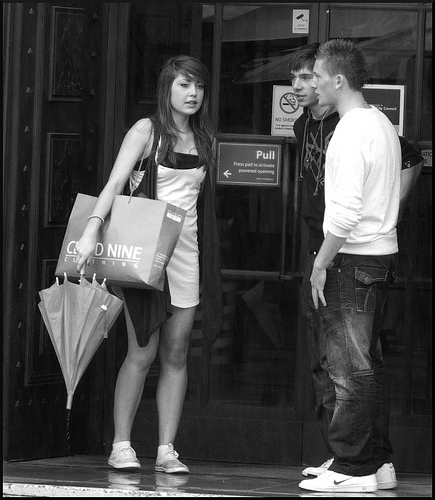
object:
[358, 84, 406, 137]
sign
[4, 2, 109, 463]
door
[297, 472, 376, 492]
sneaker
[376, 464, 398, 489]
sneaker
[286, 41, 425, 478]
guy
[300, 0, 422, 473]
door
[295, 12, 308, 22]
camera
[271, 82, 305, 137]
sign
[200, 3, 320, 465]
door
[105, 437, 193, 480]
sneakers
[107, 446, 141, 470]
feet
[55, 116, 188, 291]
bag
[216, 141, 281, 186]
sign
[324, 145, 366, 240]
sleeve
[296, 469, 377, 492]
nike shoes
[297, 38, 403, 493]
boy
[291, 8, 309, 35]
notice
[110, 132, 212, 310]
dress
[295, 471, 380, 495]
sneaker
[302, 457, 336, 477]
sneaker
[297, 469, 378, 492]
feet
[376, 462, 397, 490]
feet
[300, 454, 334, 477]
feet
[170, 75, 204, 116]
face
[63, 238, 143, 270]
white writing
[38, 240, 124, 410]
umbrella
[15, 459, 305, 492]
wet sidewalk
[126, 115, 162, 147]
shoulder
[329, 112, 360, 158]
shoulder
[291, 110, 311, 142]
shoulder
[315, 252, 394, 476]
blue jeans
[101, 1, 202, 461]
door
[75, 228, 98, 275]
hand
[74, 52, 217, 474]
girl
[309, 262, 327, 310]
hand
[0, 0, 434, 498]
business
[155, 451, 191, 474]
feet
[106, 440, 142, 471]
shoes